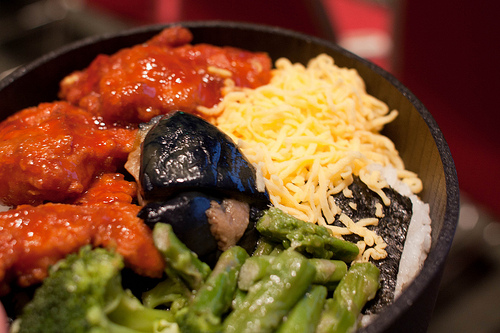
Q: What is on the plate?
A: Food.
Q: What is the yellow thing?
A: Cheese.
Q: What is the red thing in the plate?
A: Tomatoes.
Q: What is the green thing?
A: String beans.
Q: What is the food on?
A: A plate.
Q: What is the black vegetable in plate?
A: Eggplant.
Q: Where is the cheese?
A: On plate.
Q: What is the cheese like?
A: Grated.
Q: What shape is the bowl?
A: Round.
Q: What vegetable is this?
A: Broccoli.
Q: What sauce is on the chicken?
A: Red sauce.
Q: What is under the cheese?
A: White rice.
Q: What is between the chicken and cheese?
A: Olives.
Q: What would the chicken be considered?
A: Spicy.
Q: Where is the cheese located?
A: Right side of dish.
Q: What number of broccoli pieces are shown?
A: 1.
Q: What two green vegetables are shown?
A: Asparagus and broccoli.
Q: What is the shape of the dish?
A: Round.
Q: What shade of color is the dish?
A: Black.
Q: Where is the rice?
A: Under the rest of the food.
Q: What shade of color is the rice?
A: White.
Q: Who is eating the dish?
A: No One is shown.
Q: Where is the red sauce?
A: On the food to the left on dish.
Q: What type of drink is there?
A: There is no drink.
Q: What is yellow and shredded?
A: Cheese.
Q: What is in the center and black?
A: Mushroom.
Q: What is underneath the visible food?
A: Rice.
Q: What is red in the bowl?
A: Chicken.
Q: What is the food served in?
A: A wooden bowl.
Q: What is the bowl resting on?
A: A table.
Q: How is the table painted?
A: Red.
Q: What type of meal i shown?
A: Chinese.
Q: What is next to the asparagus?
A: Broccoli.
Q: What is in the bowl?
A: Cooked food.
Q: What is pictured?
A: A food dish.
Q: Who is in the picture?
A: No one.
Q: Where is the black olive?
A: In the center.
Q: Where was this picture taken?
A: Close to a bowl of food.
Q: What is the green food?
A: Asparagus.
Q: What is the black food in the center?
A: An olive.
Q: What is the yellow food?
A: Cheese.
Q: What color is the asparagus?
A: Green.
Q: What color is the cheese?
A: Yellow.